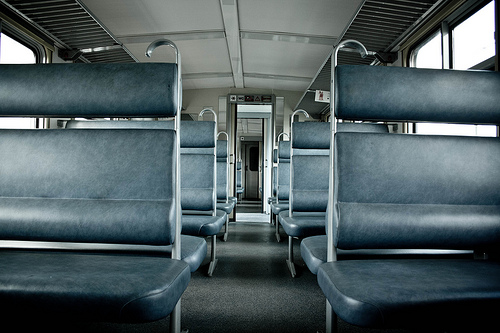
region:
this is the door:
[227, 96, 274, 198]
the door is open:
[232, 99, 273, 179]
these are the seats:
[287, 63, 434, 278]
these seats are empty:
[287, 38, 454, 249]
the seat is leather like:
[377, 259, 452, 313]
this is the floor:
[215, 260, 286, 324]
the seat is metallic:
[330, 36, 367, 63]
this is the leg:
[273, 237, 303, 284]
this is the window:
[460, 13, 493, 48]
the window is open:
[453, 10, 494, 57]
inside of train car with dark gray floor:
[11, 220, 486, 326]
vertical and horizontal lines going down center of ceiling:
[85, 0, 339, 101]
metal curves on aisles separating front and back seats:
[120, 15, 372, 330]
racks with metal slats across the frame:
[20, 0, 130, 57]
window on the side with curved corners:
[0, 21, 45, 136]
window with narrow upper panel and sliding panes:
[406, 7, 491, 67]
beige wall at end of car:
[181, 86, 296, 128]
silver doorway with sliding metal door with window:
[225, 91, 275, 216]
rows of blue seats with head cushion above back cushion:
[5, 60, 495, 310]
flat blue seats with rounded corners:
[318, 260, 495, 317]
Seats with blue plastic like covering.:
[2, 35, 497, 331]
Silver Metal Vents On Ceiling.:
[2, 0, 447, 118]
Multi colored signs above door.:
[227, 93, 275, 222]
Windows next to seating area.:
[313, 0, 496, 328]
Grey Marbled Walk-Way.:
[177, 220, 336, 331]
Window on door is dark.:
[247, 142, 261, 172]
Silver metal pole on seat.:
[2, 36, 182, 331]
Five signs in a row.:
[227, 93, 272, 105]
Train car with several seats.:
[0, 1, 498, 331]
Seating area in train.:
[0, 0, 498, 332]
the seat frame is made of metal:
[1, 40, 185, 329]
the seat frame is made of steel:
[4, 38, 193, 325]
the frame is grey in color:
[2, 40, 184, 331]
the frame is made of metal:
[321, 37, 492, 324]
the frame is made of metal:
[47, 105, 222, 271]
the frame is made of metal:
[283, 109, 403, 285]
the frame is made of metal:
[273, 130, 292, 247]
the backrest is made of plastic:
[0, 66, 187, 236]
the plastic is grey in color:
[1, 65, 185, 247]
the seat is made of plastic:
[2, 250, 204, 307]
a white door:
[244, 143, 261, 196]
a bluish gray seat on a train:
[322, 59, 494, 319]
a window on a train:
[447, 4, 497, 69]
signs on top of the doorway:
[236, 96, 272, 106]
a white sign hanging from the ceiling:
[315, 91, 330, 101]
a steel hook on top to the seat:
[142, 36, 182, 58]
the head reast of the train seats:
[0, 63, 177, 115]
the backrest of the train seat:
[5, 129, 175, 243]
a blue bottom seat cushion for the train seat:
[4, 251, 190, 319]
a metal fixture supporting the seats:
[204, 238, 222, 275]